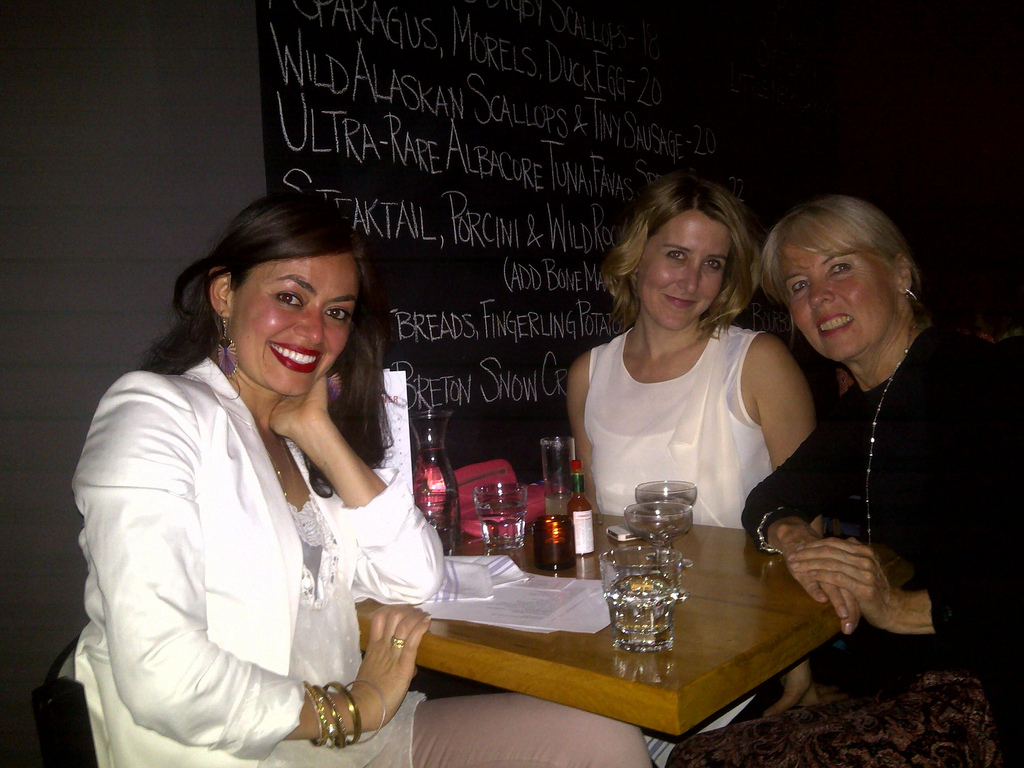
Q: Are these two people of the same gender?
A: Yes, all the people are female.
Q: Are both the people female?
A: Yes, all the people are female.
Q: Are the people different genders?
A: No, all the people are female.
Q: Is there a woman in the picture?
A: Yes, there is a woman.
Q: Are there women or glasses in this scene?
A: Yes, there is a woman.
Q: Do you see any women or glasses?
A: Yes, there is a woman.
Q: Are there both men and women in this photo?
A: No, there is a woman but no men.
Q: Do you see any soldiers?
A: No, there are no soldiers.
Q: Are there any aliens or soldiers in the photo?
A: No, there are no soldiers or aliens.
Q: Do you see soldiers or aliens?
A: No, there are no soldiers or aliens.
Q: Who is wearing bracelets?
A: The woman is wearing bracelets.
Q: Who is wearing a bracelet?
A: The woman is wearing a bracelet.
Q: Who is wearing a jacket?
A: The woman is wearing a jacket.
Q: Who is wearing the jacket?
A: The woman is wearing a jacket.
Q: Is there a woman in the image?
A: Yes, there is a woman.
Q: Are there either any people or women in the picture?
A: Yes, there is a woman.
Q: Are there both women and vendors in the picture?
A: No, there is a woman but no vendors.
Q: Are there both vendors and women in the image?
A: No, there is a woman but no vendors.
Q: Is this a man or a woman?
A: This is a woman.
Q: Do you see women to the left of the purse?
A: No, the woman is to the right of the purse.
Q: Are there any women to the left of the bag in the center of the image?
A: No, the woman is to the right of the purse.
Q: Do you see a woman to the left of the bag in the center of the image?
A: No, the woman is to the right of the purse.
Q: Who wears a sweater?
A: The woman wears a sweater.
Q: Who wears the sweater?
A: The woman wears a sweater.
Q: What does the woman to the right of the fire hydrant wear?
A: The woman wears a sweater.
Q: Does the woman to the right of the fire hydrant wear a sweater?
A: Yes, the woman wears a sweater.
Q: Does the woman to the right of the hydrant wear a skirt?
A: No, the woman wears a sweater.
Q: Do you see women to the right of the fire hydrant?
A: Yes, there is a woman to the right of the fire hydrant.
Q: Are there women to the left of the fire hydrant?
A: No, the woman is to the right of the fire hydrant.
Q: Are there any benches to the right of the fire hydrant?
A: No, there is a woman to the right of the fire hydrant.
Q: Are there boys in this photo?
A: No, there are no boys.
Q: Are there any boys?
A: No, there are no boys.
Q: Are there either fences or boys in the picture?
A: No, there are no boys or fences.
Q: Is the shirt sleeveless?
A: Yes, the shirt is sleeveless.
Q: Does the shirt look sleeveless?
A: Yes, the shirt is sleeveless.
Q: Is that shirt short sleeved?
A: No, the shirt is sleeveless.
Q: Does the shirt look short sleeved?
A: No, the shirt is sleeveless.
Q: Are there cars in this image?
A: No, there are no cars.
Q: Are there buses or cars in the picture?
A: No, there are no cars or buses.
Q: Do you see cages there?
A: No, there are no cages.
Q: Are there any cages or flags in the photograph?
A: No, there are no cages or flags.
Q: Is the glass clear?
A: Yes, the glass is clear.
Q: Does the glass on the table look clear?
A: Yes, the glass is clear.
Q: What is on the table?
A: The glass is on the table.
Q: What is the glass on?
A: The glass is on the table.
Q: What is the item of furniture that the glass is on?
A: The piece of furniture is a table.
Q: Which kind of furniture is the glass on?
A: The glass is on the table.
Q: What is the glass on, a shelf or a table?
A: The glass is on a table.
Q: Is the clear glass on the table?
A: Yes, the glass is on the table.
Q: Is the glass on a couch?
A: No, the glass is on the table.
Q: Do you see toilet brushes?
A: No, there are no toilet brushes.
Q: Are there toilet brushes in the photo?
A: No, there are no toilet brushes.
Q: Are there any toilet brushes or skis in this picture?
A: No, there are no toilet brushes or skis.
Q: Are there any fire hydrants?
A: Yes, there is a fire hydrant.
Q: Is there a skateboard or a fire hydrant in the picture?
A: Yes, there is a fire hydrant.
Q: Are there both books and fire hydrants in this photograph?
A: No, there is a fire hydrant but no books.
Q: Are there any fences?
A: No, there are no fences.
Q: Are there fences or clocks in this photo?
A: No, there are no fences or clocks.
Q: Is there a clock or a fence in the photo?
A: No, there are no fences or clocks.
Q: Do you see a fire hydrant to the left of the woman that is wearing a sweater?
A: Yes, there is a fire hydrant to the left of the woman.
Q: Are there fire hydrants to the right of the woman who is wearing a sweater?
A: No, the fire hydrant is to the left of the woman.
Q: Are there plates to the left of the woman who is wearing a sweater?
A: No, there is a fire hydrant to the left of the woman.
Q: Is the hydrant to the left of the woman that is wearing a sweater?
A: Yes, the hydrant is to the left of the woman.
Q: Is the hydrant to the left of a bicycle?
A: No, the hydrant is to the left of the woman.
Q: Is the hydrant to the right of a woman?
A: No, the hydrant is to the left of a woman.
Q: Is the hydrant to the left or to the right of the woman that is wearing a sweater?
A: The hydrant is to the left of the woman.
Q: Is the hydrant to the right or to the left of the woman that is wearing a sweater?
A: The hydrant is to the left of the woman.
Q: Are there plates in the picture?
A: No, there are no plates.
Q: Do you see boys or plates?
A: No, there are no plates or boys.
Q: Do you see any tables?
A: Yes, there is a table.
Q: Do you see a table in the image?
A: Yes, there is a table.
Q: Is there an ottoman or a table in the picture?
A: Yes, there is a table.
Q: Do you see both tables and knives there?
A: No, there is a table but no knives.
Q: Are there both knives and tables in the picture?
A: No, there is a table but no knives.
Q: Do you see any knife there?
A: No, there are no knives.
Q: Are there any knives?
A: No, there are no knives.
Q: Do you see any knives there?
A: No, there are no knives.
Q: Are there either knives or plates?
A: No, there are no knives or plates.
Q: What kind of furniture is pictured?
A: The furniture is a table.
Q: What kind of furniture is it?
A: The piece of furniture is a table.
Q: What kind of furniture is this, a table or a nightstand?
A: This is a table.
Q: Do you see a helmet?
A: No, there are no helmets.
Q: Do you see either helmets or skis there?
A: No, there are no helmets or skis.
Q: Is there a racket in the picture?
A: No, there are no rackets.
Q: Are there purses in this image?
A: Yes, there is a purse.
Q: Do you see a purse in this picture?
A: Yes, there is a purse.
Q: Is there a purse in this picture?
A: Yes, there is a purse.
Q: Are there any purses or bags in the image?
A: Yes, there is a purse.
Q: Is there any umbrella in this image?
A: No, there are no umbrellas.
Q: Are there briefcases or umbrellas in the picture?
A: No, there are no umbrellas or briefcases.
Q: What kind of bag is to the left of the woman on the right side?
A: The bag is a purse.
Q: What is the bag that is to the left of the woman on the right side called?
A: The bag is a purse.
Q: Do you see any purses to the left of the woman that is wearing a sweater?
A: Yes, there is a purse to the left of the woman.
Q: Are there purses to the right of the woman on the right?
A: No, the purse is to the left of the woman.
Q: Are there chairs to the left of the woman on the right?
A: No, there is a purse to the left of the woman.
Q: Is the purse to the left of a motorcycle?
A: No, the purse is to the left of the woman.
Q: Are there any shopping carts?
A: No, there are no shopping carts.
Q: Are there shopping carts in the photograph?
A: No, there are no shopping carts.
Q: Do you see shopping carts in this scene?
A: No, there are no shopping carts.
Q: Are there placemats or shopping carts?
A: No, there are no shopping carts or placemats.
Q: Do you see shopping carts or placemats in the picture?
A: No, there are no shopping carts or placemats.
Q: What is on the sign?
A: The letter is on the sign.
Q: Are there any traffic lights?
A: No, there are no traffic lights.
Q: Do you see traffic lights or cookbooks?
A: No, there are no traffic lights or cookbooks.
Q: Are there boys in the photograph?
A: No, there are no boys.